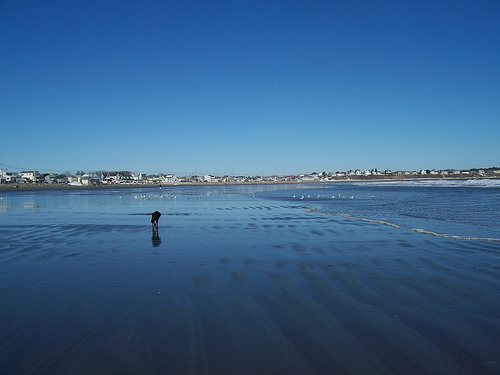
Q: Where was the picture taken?
A: It was taken at the lake.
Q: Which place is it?
A: It is a lake.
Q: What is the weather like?
A: It is cloudless.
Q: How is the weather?
A: It is cloudless.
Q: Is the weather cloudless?
A: Yes, it is cloudless.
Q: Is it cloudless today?
A: Yes, it is cloudless.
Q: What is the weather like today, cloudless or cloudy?
A: It is cloudless.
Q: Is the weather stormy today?
A: No, it is cloudless.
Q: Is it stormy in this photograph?
A: No, it is cloudless.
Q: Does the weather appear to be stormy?
A: No, it is cloudless.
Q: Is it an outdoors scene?
A: Yes, it is outdoors.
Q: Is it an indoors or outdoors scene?
A: It is outdoors.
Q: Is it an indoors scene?
A: No, it is outdoors.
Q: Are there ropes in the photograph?
A: No, there are no ropes.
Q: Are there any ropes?
A: No, there are no ropes.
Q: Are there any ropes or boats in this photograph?
A: No, there are no ropes or boats.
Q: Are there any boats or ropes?
A: No, there are no ropes or boats.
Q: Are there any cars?
A: No, there are no cars.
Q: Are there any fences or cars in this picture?
A: No, there are no cars or fences.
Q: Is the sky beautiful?
A: Yes, the sky is beautiful.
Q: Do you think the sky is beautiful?
A: Yes, the sky is beautiful.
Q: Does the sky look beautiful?
A: Yes, the sky is beautiful.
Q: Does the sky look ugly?
A: No, the sky is beautiful.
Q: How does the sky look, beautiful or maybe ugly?
A: The sky is beautiful.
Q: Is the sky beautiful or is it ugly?
A: The sky is beautiful.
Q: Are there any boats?
A: No, there are no boats.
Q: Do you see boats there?
A: No, there are no boats.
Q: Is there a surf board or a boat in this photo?
A: No, there are no boats or surfboards.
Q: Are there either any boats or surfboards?
A: No, there are no boats or surfboards.